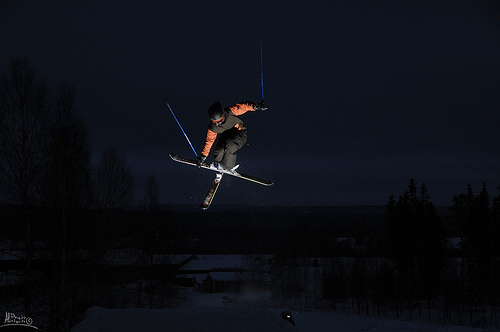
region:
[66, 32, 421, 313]
a skier in the air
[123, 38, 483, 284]
a skier in the air at night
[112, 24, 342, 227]
a skier with skies crossed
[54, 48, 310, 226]
a skies with black and orange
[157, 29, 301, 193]
black and orange jacket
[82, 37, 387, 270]
a snowboard with poles in air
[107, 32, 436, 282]
a man in the air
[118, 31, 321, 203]
a man in the air at night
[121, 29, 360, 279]
a person in the air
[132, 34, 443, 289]
a person in the air at night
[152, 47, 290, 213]
Snow skier in the air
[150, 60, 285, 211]
Snow skier lit up with a spotlight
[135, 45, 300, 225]
Snow skier sailing through the air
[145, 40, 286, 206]
Snow skier jumping through the air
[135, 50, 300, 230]
Snow skier performing a jump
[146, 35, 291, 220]
Snow skier above the ground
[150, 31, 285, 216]
Snow skier in mid air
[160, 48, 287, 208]
Snow skier in the middle of the jump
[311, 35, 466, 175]
Dark nighttime sky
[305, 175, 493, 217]
Horizon of a winter night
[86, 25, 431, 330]
a man doing a trick in the air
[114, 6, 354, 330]
a man doing a stunt in the sky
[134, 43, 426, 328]
a man in the sky at night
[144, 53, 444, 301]
a skier doing a trick in the air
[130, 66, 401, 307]
a skier with skies crossed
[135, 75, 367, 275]
a skier wearing helmet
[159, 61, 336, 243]
a skeir wearing jacket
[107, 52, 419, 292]
a skier at night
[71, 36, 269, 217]
a man is skiing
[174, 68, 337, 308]
a man is skiing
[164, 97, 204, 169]
long blue ski pole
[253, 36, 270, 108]
long blue ski pole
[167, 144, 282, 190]
long black ski in the air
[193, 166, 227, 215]
long black ski in the air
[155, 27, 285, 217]
person wearing skis in the air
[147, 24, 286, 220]
person wearing orange and black clothes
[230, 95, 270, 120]
arm of a person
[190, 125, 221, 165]
arm of a person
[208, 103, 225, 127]
black helmet on a person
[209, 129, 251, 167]
pair of black pants